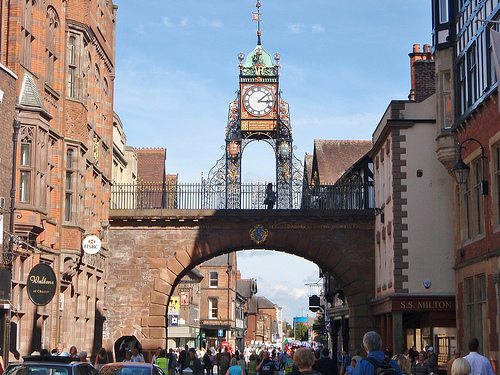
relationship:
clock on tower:
[245, 80, 275, 124] [222, 3, 307, 208]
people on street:
[177, 341, 381, 368] [16, 322, 481, 374]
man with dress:
[469, 336, 494, 375] [470, 355, 490, 372]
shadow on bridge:
[208, 202, 414, 288] [110, 176, 369, 250]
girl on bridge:
[262, 183, 280, 213] [110, 176, 369, 250]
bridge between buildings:
[110, 176, 369, 250] [368, 92, 470, 324]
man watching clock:
[469, 336, 494, 375] [245, 80, 275, 124]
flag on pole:
[253, 12, 259, 22] [250, 5, 265, 53]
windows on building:
[61, 146, 80, 223] [7, 6, 113, 348]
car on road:
[100, 359, 167, 373] [16, 322, 481, 374]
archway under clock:
[228, 104, 293, 210] [245, 80, 275, 124]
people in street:
[177, 341, 381, 368] [16, 322, 481, 374]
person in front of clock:
[262, 183, 280, 213] [245, 80, 275, 124]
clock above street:
[245, 80, 275, 124] [16, 322, 481, 374]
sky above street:
[115, 2, 443, 174] [16, 322, 481, 374]